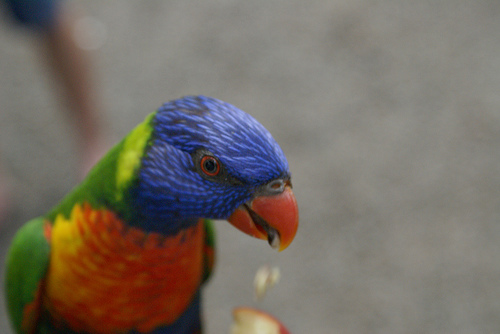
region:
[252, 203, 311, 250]
Bird has red beak.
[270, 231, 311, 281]
Tip of beak is yellow.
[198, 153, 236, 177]
Bird has red eye.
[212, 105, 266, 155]
Bird has blue head.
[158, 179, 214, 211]
Bird has blue cheek.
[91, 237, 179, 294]
Bird has orange chest.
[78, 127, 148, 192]
Back of bird's neck is green.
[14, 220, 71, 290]
Bird has green wing.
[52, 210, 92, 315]
Yellow feathers on bird's side.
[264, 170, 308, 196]
Bird's nose holes are above beak.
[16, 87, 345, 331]
a carrot eating a seed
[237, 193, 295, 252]
his beak is orange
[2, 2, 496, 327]
the wall is grey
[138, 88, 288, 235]
his head is blue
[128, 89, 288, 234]
the bird's head is black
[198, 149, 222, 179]
the eye is red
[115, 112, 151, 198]
a yellow strip on the neck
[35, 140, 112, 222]
the back is green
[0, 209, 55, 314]
the right wing is green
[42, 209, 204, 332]
the breast is yellow, orange, and red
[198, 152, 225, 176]
birds black eye ball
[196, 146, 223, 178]
red ring around birds eye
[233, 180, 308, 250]
orange beak on bird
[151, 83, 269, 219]
blue color on birds head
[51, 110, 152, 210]
green feathers for birds back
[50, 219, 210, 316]
yellow and orange feathers on bird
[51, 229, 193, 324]
yellow and orange feathers for birds chest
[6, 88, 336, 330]
tropical colored bird feathers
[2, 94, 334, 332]
multi colored feathered bird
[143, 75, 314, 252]
blue with black accent feathers on birds head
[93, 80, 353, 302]
head of the bird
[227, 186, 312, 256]
beak of the bird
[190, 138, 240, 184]
eye of the bird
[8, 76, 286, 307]
blue, green and orange bird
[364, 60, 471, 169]
blurry background of the photo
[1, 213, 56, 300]
green part of the bird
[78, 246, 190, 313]
orange body of the bird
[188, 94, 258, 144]
blue head of the bird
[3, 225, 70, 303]
wing of the bird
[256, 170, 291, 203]
nostril on the bird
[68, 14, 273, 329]
This is a bird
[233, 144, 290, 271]
This is a beak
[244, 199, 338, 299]
The beak is orange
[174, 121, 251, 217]
This is an eye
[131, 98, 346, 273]
This is a head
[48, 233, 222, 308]
This is a body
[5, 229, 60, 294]
This is a wing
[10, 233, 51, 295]
This is a green wing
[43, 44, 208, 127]
This is a leg